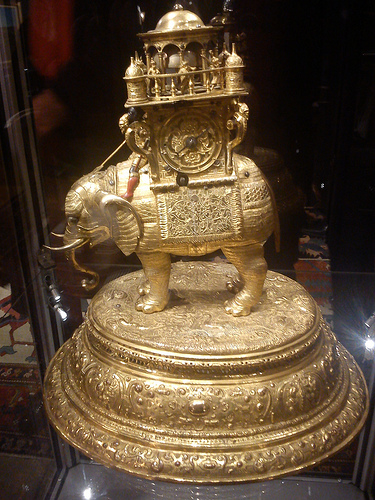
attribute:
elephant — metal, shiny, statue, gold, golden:
[41, 1, 290, 319]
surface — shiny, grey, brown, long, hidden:
[58, 450, 373, 497]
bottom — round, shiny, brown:
[43, 256, 371, 485]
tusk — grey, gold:
[41, 238, 84, 249]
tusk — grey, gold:
[52, 226, 66, 240]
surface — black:
[235, 0, 370, 304]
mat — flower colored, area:
[4, 359, 48, 464]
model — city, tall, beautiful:
[125, 0, 250, 188]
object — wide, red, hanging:
[20, 6, 91, 85]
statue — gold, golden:
[31, 263, 374, 477]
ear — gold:
[102, 196, 146, 258]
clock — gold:
[156, 108, 226, 182]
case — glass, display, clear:
[4, 0, 374, 492]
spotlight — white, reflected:
[339, 328, 373, 363]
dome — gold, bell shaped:
[38, 254, 373, 482]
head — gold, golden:
[60, 166, 144, 295]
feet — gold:
[126, 249, 271, 318]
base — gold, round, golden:
[32, 259, 371, 482]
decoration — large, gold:
[115, 1, 257, 194]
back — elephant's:
[113, 149, 245, 208]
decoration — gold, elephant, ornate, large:
[32, 0, 372, 484]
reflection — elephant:
[241, 84, 310, 209]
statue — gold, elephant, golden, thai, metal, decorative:
[34, 1, 374, 479]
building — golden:
[127, 2, 252, 189]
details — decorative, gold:
[81, 0, 286, 260]